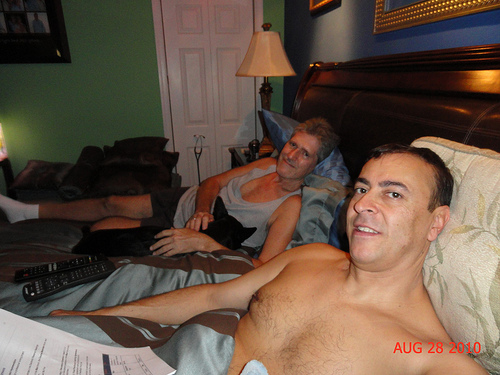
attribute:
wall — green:
[4, 5, 178, 174]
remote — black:
[10, 251, 118, 300]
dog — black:
[88, 192, 256, 246]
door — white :
[159, 0, 267, 176]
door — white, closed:
[160, 0, 258, 188]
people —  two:
[25, 80, 488, 373]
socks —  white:
[21, 210, 93, 277]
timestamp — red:
[379, 313, 491, 367]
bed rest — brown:
[288, 78, 499, 143]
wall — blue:
[295, 2, 495, 93]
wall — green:
[15, 7, 179, 131]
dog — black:
[55, 221, 303, 282]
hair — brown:
[426, 170, 460, 217]